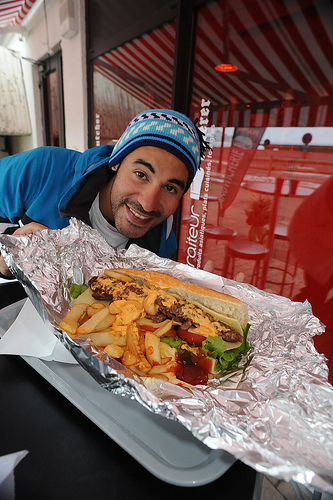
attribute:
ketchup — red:
[169, 352, 209, 386]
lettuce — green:
[205, 334, 221, 357]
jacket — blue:
[0, 146, 176, 258]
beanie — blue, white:
[105, 103, 215, 185]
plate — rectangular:
[260, 325, 286, 394]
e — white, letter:
[186, 227, 199, 236]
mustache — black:
[123, 196, 164, 223]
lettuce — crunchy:
[70, 281, 250, 369]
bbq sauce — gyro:
[176, 340, 203, 393]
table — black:
[23, 401, 128, 497]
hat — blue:
[101, 104, 201, 172]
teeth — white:
[119, 194, 179, 234]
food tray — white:
[3, 291, 252, 498]